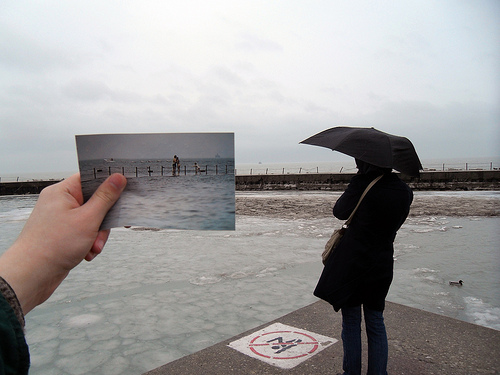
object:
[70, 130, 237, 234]
photo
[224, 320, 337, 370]
sign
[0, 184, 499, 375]
water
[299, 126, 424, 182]
umbrella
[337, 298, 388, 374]
jeans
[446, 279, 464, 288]
duck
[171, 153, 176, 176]
person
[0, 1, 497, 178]
sky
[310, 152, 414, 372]
person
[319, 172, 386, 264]
sling bag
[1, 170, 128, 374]
person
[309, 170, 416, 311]
shirt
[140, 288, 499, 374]
ground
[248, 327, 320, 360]
circle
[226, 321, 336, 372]
square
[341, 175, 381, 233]
strap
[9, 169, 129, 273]
hand